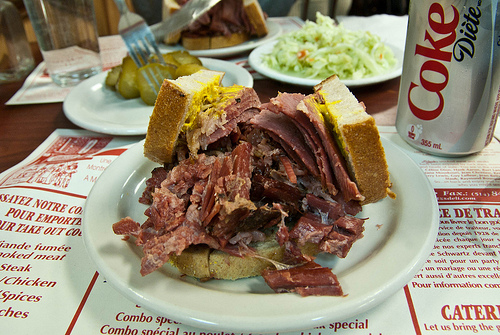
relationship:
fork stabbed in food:
[111, 0, 178, 96] [135, 65, 186, 107]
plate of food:
[78, 128, 441, 334] [123, 74, 385, 288]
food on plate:
[123, 74, 385, 288] [78, 128, 441, 334]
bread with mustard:
[143, 68, 225, 166] [186, 75, 247, 126]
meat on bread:
[125, 89, 349, 250] [155, 236, 300, 281]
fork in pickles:
[111, 0, 178, 96] [105, 48, 205, 106]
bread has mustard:
[143, 68, 225, 166] [186, 75, 247, 126]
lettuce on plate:
[267, 11, 395, 78] [246, 34, 404, 87]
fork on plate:
[111, 0, 178, 96] [62, 56, 254, 138]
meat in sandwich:
[125, 89, 349, 250] [123, 74, 385, 288]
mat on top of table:
[1, 123, 499, 334] [1, 36, 499, 333]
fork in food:
[111, 0, 178, 96] [135, 65, 186, 107]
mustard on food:
[186, 75, 247, 126] [123, 74, 385, 288]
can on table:
[395, 0, 499, 156] [1, 36, 499, 333]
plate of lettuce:
[246, 34, 404, 87] [267, 11, 395, 78]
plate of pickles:
[62, 56, 254, 138] [105, 48, 205, 106]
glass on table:
[22, 0, 103, 88] [1, 36, 499, 333]